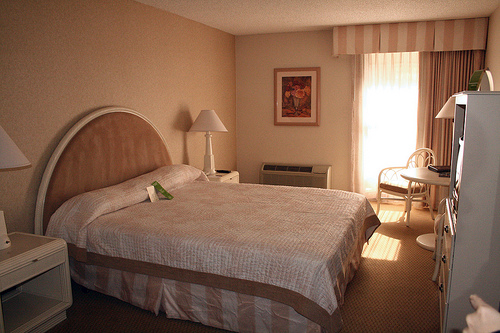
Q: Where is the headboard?
A: Against the wall.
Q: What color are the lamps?
A: White.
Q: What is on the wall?
A: A painting.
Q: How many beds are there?
A: One.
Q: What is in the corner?
A: A chair.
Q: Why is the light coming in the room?
A: The curtain is open.